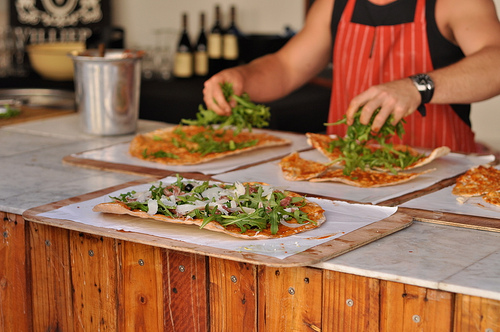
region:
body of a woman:
[193, 0, 498, 162]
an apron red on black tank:
[319, 1, 486, 151]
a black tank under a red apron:
[323, 1, 479, 148]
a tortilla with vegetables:
[91, 166, 327, 271]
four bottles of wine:
[163, 5, 247, 81]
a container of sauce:
[62, 40, 147, 142]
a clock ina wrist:
[342, 65, 449, 141]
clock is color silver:
[406, 63, 439, 125]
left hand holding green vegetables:
[333, 68, 425, 147]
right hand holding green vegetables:
[187, 63, 274, 138]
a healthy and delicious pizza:
[87, 165, 344, 255]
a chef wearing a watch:
[336, 62, 458, 139]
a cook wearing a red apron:
[318, 3, 483, 188]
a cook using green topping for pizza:
[299, 63, 439, 184]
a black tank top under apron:
[307, 2, 491, 142]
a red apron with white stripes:
[321, 0, 478, 199]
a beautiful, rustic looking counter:
[31, 142, 496, 327]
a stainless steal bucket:
[41, 33, 176, 145]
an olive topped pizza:
[143, 159, 255, 211]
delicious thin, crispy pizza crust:
[93, 159, 338, 269]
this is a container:
[76, 49, 146, 129]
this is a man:
[339, 12, 451, 73]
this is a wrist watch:
[408, 72, 436, 104]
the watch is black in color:
[413, 67, 435, 105]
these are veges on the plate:
[233, 192, 287, 222]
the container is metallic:
[77, 67, 137, 120]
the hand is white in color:
[452, 64, 492, 97]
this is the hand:
[264, 57, 301, 89]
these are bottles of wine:
[174, 5, 249, 62]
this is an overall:
[341, 31, 411, 68]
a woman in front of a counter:
[189, 1, 497, 162]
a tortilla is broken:
[268, 121, 455, 190]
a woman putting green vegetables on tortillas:
[118, 1, 498, 186]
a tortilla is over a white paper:
[42, 168, 344, 265]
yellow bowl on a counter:
[20, 28, 80, 84]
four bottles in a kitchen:
[166, 1, 245, 77]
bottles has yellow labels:
[164, 1, 246, 82]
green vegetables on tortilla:
[121, 108, 296, 168]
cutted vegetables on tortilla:
[276, 123, 452, 190]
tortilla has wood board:
[14, 162, 426, 274]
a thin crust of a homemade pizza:
[97, 173, 325, 240]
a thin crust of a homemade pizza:
[132, 123, 287, 169]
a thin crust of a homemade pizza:
[284, 148, 431, 191]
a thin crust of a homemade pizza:
[305, 129, 444, 172]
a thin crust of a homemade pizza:
[457, 160, 499, 207]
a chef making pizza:
[197, 2, 499, 150]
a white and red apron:
[327, 1, 474, 151]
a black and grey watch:
[410, 72, 437, 106]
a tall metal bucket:
[71, 48, 146, 134]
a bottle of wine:
[175, 13, 194, 75]